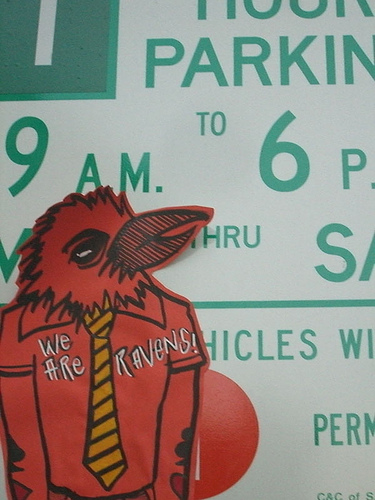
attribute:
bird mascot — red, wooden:
[1, 182, 215, 497]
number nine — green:
[5, 114, 49, 197]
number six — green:
[258, 109, 311, 192]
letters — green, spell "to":
[194, 109, 227, 137]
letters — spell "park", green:
[143, 34, 322, 89]